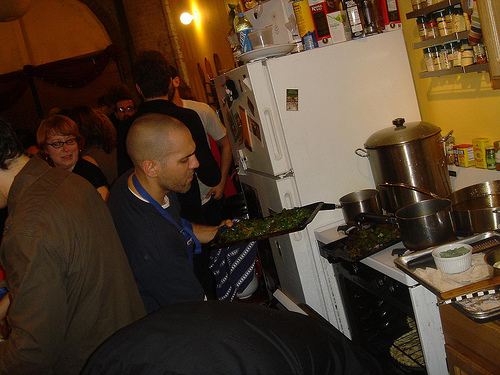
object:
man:
[106, 112, 234, 313]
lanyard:
[129, 174, 205, 255]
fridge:
[210, 29, 419, 343]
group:
[1, 51, 381, 375]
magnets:
[245, 116, 261, 142]